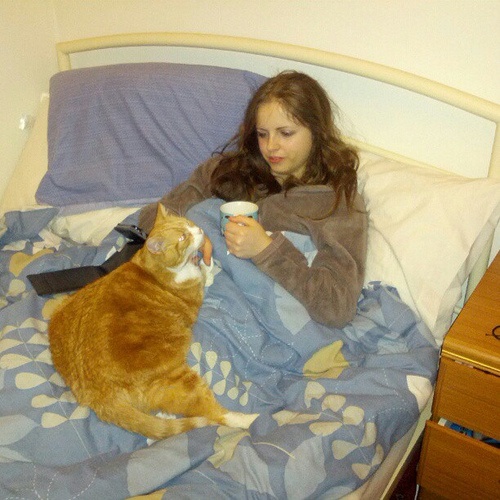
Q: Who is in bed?
A: The woman.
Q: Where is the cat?
A: In bed.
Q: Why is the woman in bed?
A: She is sick.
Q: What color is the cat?
A: Orange.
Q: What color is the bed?
A: Blue.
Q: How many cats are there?
A: One.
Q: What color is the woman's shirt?
A: Grey.